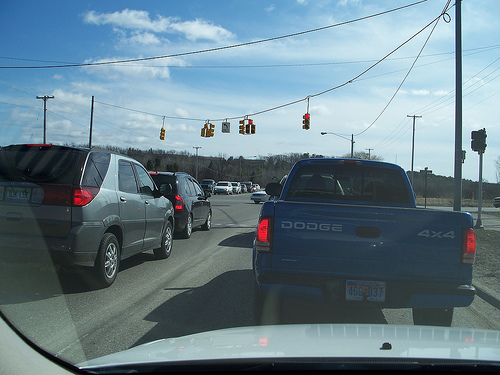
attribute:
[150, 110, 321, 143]
lights — hanging up, street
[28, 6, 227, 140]
clouds — white 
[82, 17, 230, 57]
clouds — white 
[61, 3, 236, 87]
clouds — white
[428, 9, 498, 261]
pole — tall street 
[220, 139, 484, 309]
truck — blue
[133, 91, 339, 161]
stop light — stop 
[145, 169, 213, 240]
van — black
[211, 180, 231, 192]
car — intersection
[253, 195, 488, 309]
dodge truck — 4x4 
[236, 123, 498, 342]
vehicle — white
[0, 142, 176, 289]
van — grey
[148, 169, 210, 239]
van — grey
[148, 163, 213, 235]
car — stopped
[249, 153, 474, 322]
car — stopped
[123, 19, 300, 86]
clouds — white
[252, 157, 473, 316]
truck — blue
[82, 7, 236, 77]
clouds — white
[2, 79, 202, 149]
clouds — white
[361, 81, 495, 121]
clouds — white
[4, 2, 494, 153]
sky — blue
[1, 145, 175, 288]
car — stopped, gray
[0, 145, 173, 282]
vehicle — gray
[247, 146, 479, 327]
truck — blue, stopped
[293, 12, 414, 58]
white clouds — white 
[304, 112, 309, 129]
street light — red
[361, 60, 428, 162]
clouds — white 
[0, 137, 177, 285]
gray van — grey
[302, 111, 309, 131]
light — traffic, red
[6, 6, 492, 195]
sky — blue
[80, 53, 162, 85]
clouds —  white 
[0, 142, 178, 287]
gray car — gray 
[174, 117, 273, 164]
traffic sign — white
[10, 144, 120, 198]
windows — tinted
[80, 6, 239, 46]
clouds — white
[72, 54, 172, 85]
clouds — white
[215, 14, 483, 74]
clouds — white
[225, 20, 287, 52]
sky —  blue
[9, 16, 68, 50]
sky —  blue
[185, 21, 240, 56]
clouds — white 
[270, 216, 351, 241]
lettering — white 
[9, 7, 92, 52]
sky — blue 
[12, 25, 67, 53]
sky — blue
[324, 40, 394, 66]
cloud — white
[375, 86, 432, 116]
cloud — white